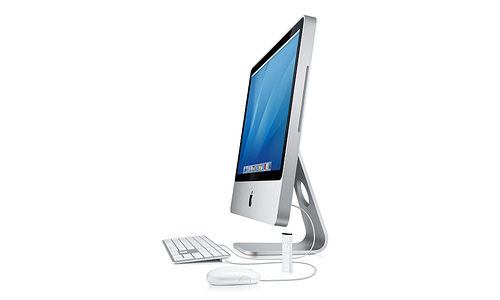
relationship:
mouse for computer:
[206, 262, 247, 299] [248, 42, 322, 195]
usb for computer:
[282, 201, 311, 220] [248, 42, 322, 195]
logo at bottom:
[245, 184, 253, 210] [200, 143, 278, 220]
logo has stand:
[245, 184, 253, 210] [290, 183, 345, 263]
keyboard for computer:
[170, 219, 228, 269] [248, 42, 322, 195]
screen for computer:
[226, 43, 335, 201] [248, 42, 322, 195]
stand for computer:
[290, 183, 345, 263] [248, 42, 322, 195]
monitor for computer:
[229, 73, 287, 129] [248, 42, 322, 195]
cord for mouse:
[291, 210, 322, 241] [206, 262, 247, 299]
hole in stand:
[293, 179, 324, 209] [290, 183, 345, 263]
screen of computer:
[226, 43, 335, 201] [248, 42, 322, 195]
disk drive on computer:
[302, 65, 314, 135] [248, 42, 322, 195]